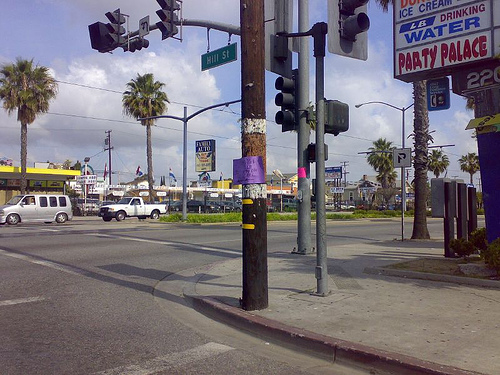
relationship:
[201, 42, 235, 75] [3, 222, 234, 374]
sign in a street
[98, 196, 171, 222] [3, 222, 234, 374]
wehicle on street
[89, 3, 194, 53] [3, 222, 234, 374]
traffic signals on street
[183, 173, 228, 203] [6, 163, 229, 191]
property in background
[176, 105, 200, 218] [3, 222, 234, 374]
pole on street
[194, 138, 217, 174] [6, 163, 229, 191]
sign in background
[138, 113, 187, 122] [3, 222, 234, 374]
lamp post on street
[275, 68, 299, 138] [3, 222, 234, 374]
signal for street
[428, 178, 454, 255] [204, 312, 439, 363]
telephone on sidewalk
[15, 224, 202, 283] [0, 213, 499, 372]
crosswalk on street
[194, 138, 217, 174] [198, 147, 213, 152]
sign says auto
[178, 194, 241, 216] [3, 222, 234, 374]
auto dealer across street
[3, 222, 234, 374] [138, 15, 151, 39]
street has a sign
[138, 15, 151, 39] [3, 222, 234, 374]
directional sign on street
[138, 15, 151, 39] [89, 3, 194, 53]
directional sign near traffic signals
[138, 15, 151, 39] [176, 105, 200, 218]
directional sign near a pole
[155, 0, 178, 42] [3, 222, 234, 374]
traffic light in street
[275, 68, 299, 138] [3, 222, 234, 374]
light in street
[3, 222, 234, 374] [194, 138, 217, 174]
street has a sign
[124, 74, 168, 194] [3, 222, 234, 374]
tree across street